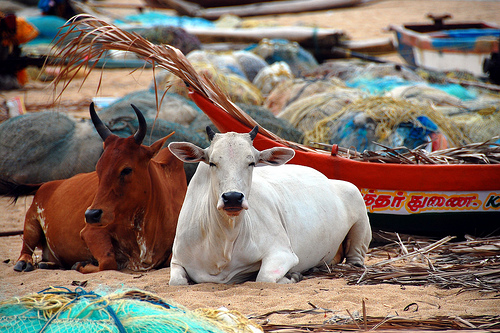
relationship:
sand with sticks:
[210, 290, 462, 313] [395, 239, 495, 289]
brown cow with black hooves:
[13, 101, 195, 274] [10, 254, 89, 273]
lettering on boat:
[352, 190, 495, 219] [175, 64, 499, 243]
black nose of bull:
[221, 190, 244, 206] [156, 119, 375, 285]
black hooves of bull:
[10, 261, 38, 274] [161, 122, 401, 275]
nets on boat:
[290, 90, 400, 152] [24, 6, 498, 261]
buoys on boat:
[290, 81, 467, 164] [24, 6, 498, 261]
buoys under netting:
[0, 287, 225, 332] [5, 274, 169, 312]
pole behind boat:
[63, 10, 346, 42] [9, 4, 354, 64]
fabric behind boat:
[29, 8, 209, 60] [9, 4, 354, 64]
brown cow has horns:
[13, 101, 195, 274] [88, 98, 146, 147]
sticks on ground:
[369, 227, 499, 322] [4, 195, 497, 330]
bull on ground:
[156, 119, 375, 285] [14, 261, 356, 314]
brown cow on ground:
[13, 101, 195, 274] [14, 261, 356, 314]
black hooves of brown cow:
[10, 261, 38, 274] [13, 101, 195, 274]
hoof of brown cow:
[70, 260, 91, 270] [13, 101, 195, 274]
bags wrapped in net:
[0, 37, 500, 185] [0, 34, 498, 192]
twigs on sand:
[1, 193, 499, 331] [6, 195, 493, 326]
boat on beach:
[386, 12, 488, 68] [1, 1, 497, 329]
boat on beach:
[175, 78, 477, 238] [1, 1, 497, 329]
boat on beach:
[11, 15, 348, 57] [1, 1, 497, 329]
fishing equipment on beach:
[1, 282, 261, 332] [1, 1, 497, 329]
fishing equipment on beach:
[304, 96, 454, 153] [1, 1, 497, 329]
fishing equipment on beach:
[89, 88, 304, 142] [1, 1, 497, 329]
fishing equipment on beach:
[0, 110, 104, 195] [1, 1, 497, 329]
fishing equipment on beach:
[252, 58, 292, 90] [1, 1, 497, 329]